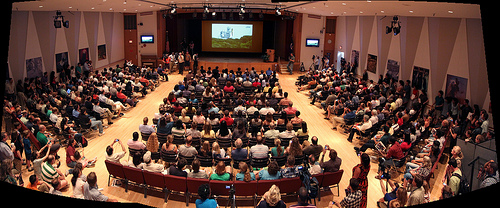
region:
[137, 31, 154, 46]
Wall mounted black flatscreen television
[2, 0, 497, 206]
People sitting in auditorium seats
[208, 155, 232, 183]
Red haired woman wearing a green shirt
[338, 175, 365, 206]
Man wearing a white and black shirt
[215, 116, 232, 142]
Woman with long black hair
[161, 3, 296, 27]
Black hanging stage light fixtures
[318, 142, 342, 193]
Man taking pictures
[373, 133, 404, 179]
Person holding a large paper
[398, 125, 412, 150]
Black haired woman wearing a red shirt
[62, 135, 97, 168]
Woman sitting on the floor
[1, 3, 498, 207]
Large auditorium of people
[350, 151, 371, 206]
Woman wearing a red and black dress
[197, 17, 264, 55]
Film playing on a movie screen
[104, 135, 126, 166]
Person taking a picture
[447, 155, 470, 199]
Man wearing a black backpack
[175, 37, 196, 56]
Two people standing on a stage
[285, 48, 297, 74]
Person standing at the stairs of a stage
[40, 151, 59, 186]
Man wearing a white and green striped shirt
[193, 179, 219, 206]
Woman in a blue shirt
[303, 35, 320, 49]
Wall mounted flat screen television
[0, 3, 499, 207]
A conference room packed with people.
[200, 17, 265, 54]
A screen with an image projected on it.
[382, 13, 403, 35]
A light fixture attached to the ceiling.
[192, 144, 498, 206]
A group of people standing in the back.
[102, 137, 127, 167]
A person using a digital camera.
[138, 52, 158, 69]
A piano with a bench in front.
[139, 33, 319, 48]
Two television screens are on the wall.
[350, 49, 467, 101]
Paintings lining the wall.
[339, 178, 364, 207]
A man wearing plaid shirt.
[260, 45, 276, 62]
A podium with a plant next to it.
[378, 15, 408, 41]
Big lights hanging from the ceiling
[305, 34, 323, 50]
A small screen at the side of stage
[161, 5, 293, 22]
Spot lights hanging from the ceiling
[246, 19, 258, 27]
Edge of the big screen on stage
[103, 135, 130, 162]
A man getting some pictures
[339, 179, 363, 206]
A man with a checkered shirt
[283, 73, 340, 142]
A narrows aisle in the middle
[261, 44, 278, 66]
A brown podium at the stage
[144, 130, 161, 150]
A long curly blonde hair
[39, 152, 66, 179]
A man in a stripe green and white shirt